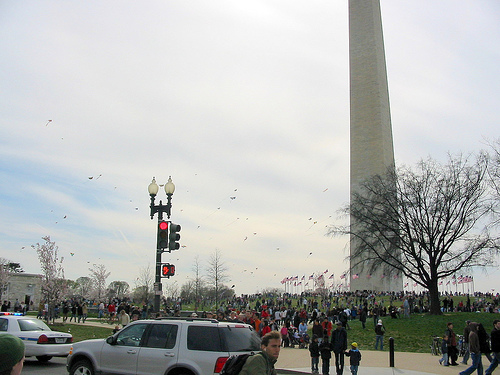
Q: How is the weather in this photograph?
A: It is cloudy.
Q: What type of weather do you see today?
A: It is cloudy.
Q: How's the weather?
A: It is cloudy.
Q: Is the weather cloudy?
A: Yes, it is cloudy.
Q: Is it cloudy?
A: Yes, it is cloudy.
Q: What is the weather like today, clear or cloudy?
A: It is cloudy.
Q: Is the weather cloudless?
A: No, it is cloudy.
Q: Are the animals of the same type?
A: Yes, all the animals are birds.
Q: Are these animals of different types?
A: No, all the animals are birds.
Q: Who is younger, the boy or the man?
A: The boy is younger than the man.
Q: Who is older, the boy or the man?
A: The man is older than the boy.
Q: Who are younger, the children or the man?
A: The children are younger than the man.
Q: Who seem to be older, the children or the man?
A: The man are older than the children.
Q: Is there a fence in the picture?
A: No, there are no fences.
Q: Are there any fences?
A: No, there are no fences.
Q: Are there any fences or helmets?
A: No, there are no fences or helmets.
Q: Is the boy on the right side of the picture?
A: Yes, the boy is on the right of the image.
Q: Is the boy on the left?
A: No, the boy is on the right of the image.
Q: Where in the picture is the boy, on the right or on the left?
A: The boy is on the right of the image.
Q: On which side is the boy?
A: The boy is on the right of the image.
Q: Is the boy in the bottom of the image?
A: Yes, the boy is in the bottom of the image.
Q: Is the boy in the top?
A: No, the boy is in the bottom of the image.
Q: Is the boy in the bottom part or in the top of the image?
A: The boy is in the bottom of the image.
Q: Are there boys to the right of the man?
A: Yes, there is a boy to the right of the man.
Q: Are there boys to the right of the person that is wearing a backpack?
A: Yes, there is a boy to the right of the man.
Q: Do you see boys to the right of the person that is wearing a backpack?
A: Yes, there is a boy to the right of the man.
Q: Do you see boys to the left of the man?
A: No, the boy is to the right of the man.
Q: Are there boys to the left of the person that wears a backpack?
A: No, the boy is to the right of the man.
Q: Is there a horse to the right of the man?
A: No, there is a boy to the right of the man.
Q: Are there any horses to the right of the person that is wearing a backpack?
A: No, there is a boy to the right of the man.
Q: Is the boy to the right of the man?
A: Yes, the boy is to the right of the man.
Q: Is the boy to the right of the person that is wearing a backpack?
A: Yes, the boy is to the right of the man.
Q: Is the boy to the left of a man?
A: No, the boy is to the right of a man.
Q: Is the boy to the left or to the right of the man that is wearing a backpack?
A: The boy is to the right of the man.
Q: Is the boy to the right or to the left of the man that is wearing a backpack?
A: The boy is to the right of the man.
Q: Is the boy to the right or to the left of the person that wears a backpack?
A: The boy is to the right of the man.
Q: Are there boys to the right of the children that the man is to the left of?
A: Yes, there is a boy to the right of the children.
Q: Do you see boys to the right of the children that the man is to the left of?
A: Yes, there is a boy to the right of the children.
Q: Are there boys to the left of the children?
A: No, the boy is to the right of the children.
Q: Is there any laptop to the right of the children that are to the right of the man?
A: No, there is a boy to the right of the kids.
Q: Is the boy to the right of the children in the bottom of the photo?
A: Yes, the boy is to the right of the kids.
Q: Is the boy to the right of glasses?
A: No, the boy is to the right of the kids.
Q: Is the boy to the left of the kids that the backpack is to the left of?
A: No, the boy is to the right of the children.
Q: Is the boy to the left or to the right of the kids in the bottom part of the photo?
A: The boy is to the right of the children.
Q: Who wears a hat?
A: The boy wears a hat.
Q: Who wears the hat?
A: The boy wears a hat.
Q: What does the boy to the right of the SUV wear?
A: The boy wears a hat.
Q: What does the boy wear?
A: The boy wears a hat.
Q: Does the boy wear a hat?
A: Yes, the boy wears a hat.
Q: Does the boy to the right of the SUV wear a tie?
A: No, the boy wears a hat.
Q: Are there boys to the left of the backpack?
A: No, the boy is to the right of the backpack.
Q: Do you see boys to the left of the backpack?
A: No, the boy is to the right of the backpack.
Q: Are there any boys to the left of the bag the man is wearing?
A: No, the boy is to the right of the backpack.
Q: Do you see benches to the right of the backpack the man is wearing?
A: No, there is a boy to the right of the backpack.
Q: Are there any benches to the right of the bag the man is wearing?
A: No, there is a boy to the right of the backpack.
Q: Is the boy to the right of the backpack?
A: Yes, the boy is to the right of the backpack.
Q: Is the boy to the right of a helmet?
A: No, the boy is to the right of the backpack.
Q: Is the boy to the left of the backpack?
A: No, the boy is to the right of the backpack.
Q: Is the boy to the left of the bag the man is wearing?
A: No, the boy is to the right of the backpack.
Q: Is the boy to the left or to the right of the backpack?
A: The boy is to the right of the backpack.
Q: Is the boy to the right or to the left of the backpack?
A: The boy is to the right of the backpack.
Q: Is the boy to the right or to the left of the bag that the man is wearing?
A: The boy is to the right of the backpack.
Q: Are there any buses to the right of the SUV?
A: No, there is a boy to the right of the SUV.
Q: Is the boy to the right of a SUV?
A: Yes, the boy is to the right of a SUV.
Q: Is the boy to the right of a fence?
A: No, the boy is to the right of a SUV.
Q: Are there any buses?
A: No, there are no buses.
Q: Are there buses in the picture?
A: No, there are no buses.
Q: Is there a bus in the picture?
A: No, there are no buses.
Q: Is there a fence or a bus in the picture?
A: No, there are no buses or fences.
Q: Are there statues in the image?
A: No, there are no statues.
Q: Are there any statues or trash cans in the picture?
A: No, there are no statues or trash cans.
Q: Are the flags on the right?
A: Yes, the flags are on the right of the image.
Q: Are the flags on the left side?
A: No, the flags are on the right of the image.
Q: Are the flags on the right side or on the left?
A: The flags are on the right of the image.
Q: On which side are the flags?
A: The flags are on the right of the image.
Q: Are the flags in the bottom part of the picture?
A: Yes, the flags are in the bottom of the image.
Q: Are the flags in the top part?
A: No, the flags are in the bottom of the image.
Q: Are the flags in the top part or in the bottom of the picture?
A: The flags are in the bottom of the image.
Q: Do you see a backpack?
A: Yes, there is a backpack.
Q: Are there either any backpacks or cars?
A: Yes, there is a backpack.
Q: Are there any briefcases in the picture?
A: No, there are no briefcases.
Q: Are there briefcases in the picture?
A: No, there are no briefcases.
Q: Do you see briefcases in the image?
A: No, there are no briefcases.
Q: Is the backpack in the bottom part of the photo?
A: Yes, the backpack is in the bottom of the image.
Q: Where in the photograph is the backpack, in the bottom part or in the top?
A: The backpack is in the bottom of the image.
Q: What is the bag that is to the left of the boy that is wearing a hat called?
A: The bag is a backpack.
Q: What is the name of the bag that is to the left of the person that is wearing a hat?
A: The bag is a backpack.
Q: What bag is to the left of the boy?
A: The bag is a backpack.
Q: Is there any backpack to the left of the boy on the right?
A: Yes, there is a backpack to the left of the boy.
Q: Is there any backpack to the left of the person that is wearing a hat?
A: Yes, there is a backpack to the left of the boy.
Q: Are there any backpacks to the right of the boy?
A: No, the backpack is to the left of the boy.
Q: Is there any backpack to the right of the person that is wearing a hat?
A: No, the backpack is to the left of the boy.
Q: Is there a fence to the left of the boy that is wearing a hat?
A: No, there is a backpack to the left of the boy.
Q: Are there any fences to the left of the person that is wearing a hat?
A: No, there is a backpack to the left of the boy.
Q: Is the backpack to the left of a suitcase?
A: No, the backpack is to the left of the boy.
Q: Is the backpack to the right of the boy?
A: No, the backpack is to the left of the boy.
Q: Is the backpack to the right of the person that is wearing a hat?
A: No, the backpack is to the left of the boy.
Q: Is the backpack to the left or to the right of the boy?
A: The backpack is to the left of the boy.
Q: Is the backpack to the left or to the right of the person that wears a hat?
A: The backpack is to the left of the boy.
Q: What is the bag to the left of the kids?
A: The bag is a backpack.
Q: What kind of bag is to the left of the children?
A: The bag is a backpack.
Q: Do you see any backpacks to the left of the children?
A: Yes, there is a backpack to the left of the children.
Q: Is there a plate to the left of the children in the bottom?
A: No, there is a backpack to the left of the children.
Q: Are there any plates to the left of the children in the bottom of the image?
A: No, there is a backpack to the left of the children.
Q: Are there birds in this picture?
A: Yes, there are birds.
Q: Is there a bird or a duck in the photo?
A: Yes, there are birds.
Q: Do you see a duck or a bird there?
A: Yes, there are birds.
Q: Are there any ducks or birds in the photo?
A: Yes, there are birds.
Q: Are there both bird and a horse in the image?
A: No, there are birds but no horses.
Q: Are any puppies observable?
A: No, there are no puppies.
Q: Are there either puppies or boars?
A: No, there are no puppies or boars.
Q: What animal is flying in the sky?
A: The birds are flying in the sky.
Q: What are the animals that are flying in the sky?
A: The animals are birds.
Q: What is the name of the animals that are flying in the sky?
A: The animals are birds.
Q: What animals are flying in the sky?
A: The animals are birds.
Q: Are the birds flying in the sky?
A: Yes, the birds are flying in the sky.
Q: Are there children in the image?
A: Yes, there are children.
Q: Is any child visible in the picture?
A: Yes, there are children.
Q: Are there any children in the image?
A: Yes, there are children.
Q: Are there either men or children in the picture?
A: Yes, there are children.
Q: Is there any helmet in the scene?
A: No, there are no helmets.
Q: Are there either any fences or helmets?
A: No, there are no helmets or fences.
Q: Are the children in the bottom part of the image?
A: Yes, the children are in the bottom of the image.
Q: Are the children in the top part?
A: No, the children are in the bottom of the image.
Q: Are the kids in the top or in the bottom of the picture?
A: The kids are in the bottom of the image.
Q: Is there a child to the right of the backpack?
A: Yes, there are children to the right of the backpack.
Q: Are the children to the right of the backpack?
A: Yes, the children are to the right of the backpack.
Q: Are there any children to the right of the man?
A: Yes, there are children to the right of the man.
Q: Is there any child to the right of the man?
A: Yes, there are children to the right of the man.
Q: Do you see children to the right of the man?
A: Yes, there are children to the right of the man.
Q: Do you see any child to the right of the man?
A: Yes, there are children to the right of the man.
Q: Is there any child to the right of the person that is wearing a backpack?
A: Yes, there are children to the right of the man.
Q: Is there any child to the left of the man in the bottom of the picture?
A: No, the children are to the right of the man.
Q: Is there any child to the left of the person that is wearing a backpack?
A: No, the children are to the right of the man.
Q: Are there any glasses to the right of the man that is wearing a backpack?
A: No, there are children to the right of the man.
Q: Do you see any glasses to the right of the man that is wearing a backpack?
A: No, there are children to the right of the man.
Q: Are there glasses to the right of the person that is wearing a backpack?
A: No, there are children to the right of the man.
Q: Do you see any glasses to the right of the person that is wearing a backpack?
A: No, there are children to the right of the man.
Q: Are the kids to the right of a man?
A: Yes, the kids are to the right of a man.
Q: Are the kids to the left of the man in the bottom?
A: No, the kids are to the right of the man.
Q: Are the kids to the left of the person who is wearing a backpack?
A: No, the kids are to the right of the man.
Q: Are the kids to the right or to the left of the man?
A: The kids are to the right of the man.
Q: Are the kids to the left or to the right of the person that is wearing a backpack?
A: The kids are to the right of the man.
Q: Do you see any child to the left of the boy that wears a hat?
A: Yes, there are children to the left of the boy.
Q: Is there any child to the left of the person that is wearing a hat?
A: Yes, there are children to the left of the boy.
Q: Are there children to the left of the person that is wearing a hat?
A: Yes, there are children to the left of the boy.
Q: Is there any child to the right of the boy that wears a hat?
A: No, the children are to the left of the boy.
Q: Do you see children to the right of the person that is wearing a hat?
A: No, the children are to the left of the boy.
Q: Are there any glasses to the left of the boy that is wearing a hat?
A: No, there are children to the left of the boy.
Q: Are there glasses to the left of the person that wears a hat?
A: No, there are children to the left of the boy.